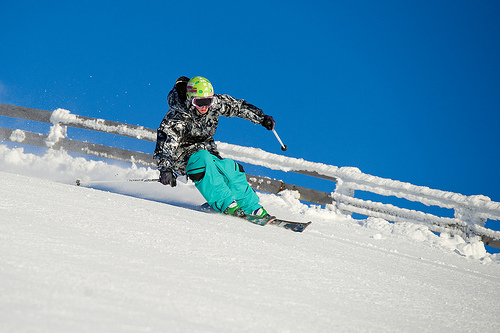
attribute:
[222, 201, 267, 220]
ski boots — green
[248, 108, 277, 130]
glove — black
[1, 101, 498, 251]
railing — metal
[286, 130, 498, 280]
fence — covered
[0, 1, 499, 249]
sky — blue, clear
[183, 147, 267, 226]
ski pants — colored, turquoise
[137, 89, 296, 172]
jacket — white, black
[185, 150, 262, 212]
pants — blue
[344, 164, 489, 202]
snow — white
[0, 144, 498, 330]
snow — white